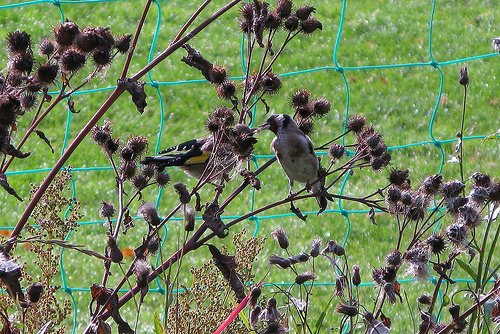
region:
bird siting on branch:
[261, 96, 339, 210]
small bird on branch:
[260, 98, 345, 219]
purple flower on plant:
[391, 161, 415, 201]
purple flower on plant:
[345, 111, 375, 135]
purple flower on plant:
[298, 13, 328, 41]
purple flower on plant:
[117, 132, 149, 173]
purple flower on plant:
[80, 121, 115, 158]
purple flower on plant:
[5, 25, 35, 52]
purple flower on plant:
[50, 43, 85, 84]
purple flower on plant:
[81, 28, 113, 55]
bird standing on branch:
[243, 92, 398, 235]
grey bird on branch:
[58, 9, 88, 49]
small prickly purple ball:
[102, 18, 144, 69]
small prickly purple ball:
[2, 249, 44, 310]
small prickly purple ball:
[131, 255, 165, 300]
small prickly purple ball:
[137, 208, 168, 235]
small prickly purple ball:
[267, 222, 297, 253]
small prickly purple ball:
[377, 236, 407, 290]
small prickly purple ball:
[477, 169, 498, 211]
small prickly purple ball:
[415, 161, 472, 213]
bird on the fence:
[240, 111, 333, 219]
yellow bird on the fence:
[134, 117, 273, 180]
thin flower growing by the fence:
[453, 59, 471, 184]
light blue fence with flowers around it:
[0, 0, 495, 330]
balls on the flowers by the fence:
[212, 77, 233, 97]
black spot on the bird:
[280, 108, 295, 131]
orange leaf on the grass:
[117, 243, 138, 258]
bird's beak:
[251, 117, 269, 134]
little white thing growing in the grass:
[413, 106, 422, 117]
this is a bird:
[249, 105, 363, 198]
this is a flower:
[272, 221, 311, 273]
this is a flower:
[319, 238, 350, 270]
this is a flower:
[84, 112, 114, 155]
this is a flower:
[416, 160, 441, 200]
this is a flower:
[76, 25, 106, 67]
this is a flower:
[114, 245, 171, 310]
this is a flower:
[201, 54, 231, 89]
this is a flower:
[87, 120, 127, 170]